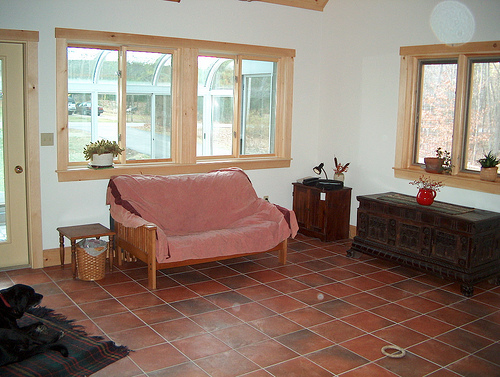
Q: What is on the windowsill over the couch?
A: A plant in a pot.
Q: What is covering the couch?
A: A blanket.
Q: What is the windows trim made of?
A: Wood.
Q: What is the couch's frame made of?
A: Wood.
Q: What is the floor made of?
A: Tile.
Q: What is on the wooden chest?
A: A flower pot.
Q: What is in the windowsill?
A: Potted plants.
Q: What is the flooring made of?
A: Tile.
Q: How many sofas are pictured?
A: One.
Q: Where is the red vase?
A: On the curio.